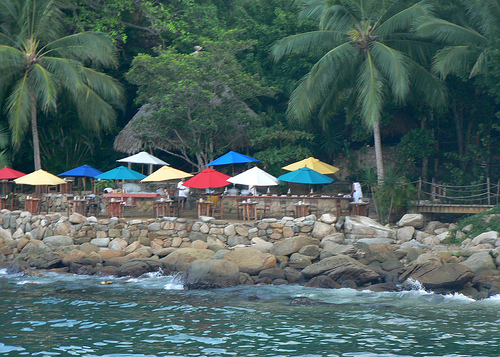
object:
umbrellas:
[205, 149, 257, 169]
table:
[186, 192, 359, 203]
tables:
[33, 190, 165, 202]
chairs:
[241, 195, 266, 221]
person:
[348, 177, 363, 202]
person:
[175, 178, 191, 204]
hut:
[325, 144, 421, 196]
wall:
[334, 145, 411, 186]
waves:
[0, 262, 185, 291]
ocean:
[0, 266, 497, 357]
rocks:
[180, 256, 242, 290]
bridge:
[406, 177, 500, 216]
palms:
[270, 0, 452, 190]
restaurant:
[0, 146, 367, 219]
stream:
[441, 217, 460, 224]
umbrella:
[272, 165, 332, 188]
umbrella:
[226, 164, 282, 189]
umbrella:
[178, 166, 236, 191]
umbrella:
[137, 165, 195, 184]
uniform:
[353, 180, 364, 201]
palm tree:
[0, 0, 124, 172]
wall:
[0, 209, 500, 295]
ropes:
[422, 182, 488, 189]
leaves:
[37, 54, 84, 104]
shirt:
[176, 182, 190, 197]